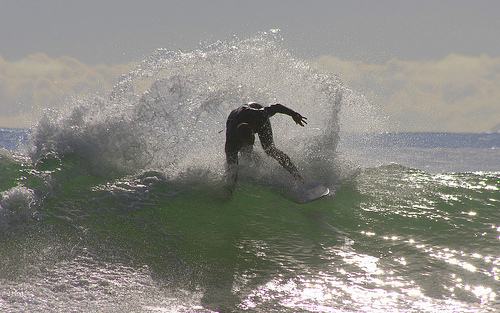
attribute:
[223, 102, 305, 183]
wetsuit — black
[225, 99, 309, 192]
person — bended, crouched, bent over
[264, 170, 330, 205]
surfboard — white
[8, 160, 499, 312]
water — choppy, splashing, green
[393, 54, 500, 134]
cloud — puffy, white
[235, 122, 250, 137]
hair — dark brown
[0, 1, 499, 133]
sky — blue, white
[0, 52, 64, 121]
cloud — white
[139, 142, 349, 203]
wave — white